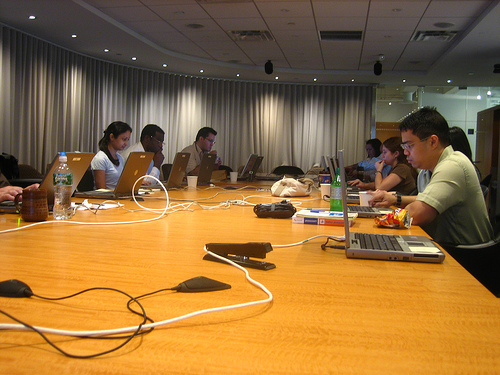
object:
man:
[120, 124, 164, 189]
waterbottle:
[52, 152, 74, 220]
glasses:
[401, 138, 429, 150]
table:
[31, 145, 488, 372]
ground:
[397, 151, 437, 193]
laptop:
[326, 155, 367, 192]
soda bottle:
[329, 168, 347, 211]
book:
[292, 208, 359, 227]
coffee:
[187, 176, 198, 191]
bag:
[374, 208, 413, 229]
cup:
[13, 189, 48, 222]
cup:
[186, 177, 197, 192]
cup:
[229, 172, 238, 185]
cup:
[320, 183, 331, 199]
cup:
[359, 191, 374, 206]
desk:
[1, 180, 498, 375]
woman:
[90, 121, 151, 191]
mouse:
[0, 279, 33, 299]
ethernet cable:
[0, 174, 323, 360]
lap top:
[227, 154, 258, 179]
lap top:
[338, 149, 446, 265]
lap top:
[75, 151, 155, 200]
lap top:
[140, 152, 192, 190]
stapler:
[203, 242, 277, 271]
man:
[368, 106, 500, 297]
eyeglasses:
[150, 136, 165, 146]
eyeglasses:
[205, 137, 216, 144]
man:
[180, 127, 222, 180]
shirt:
[415, 145, 496, 259]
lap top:
[0, 152, 95, 214]